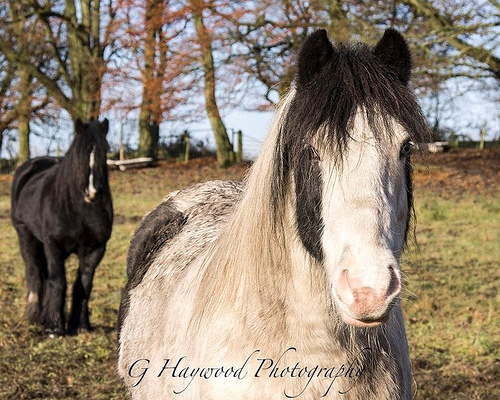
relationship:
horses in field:
[3, 66, 443, 317] [416, 180, 492, 331]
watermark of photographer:
[105, 353, 384, 387] [129, 357, 254, 391]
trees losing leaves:
[39, 17, 288, 108] [158, 10, 197, 20]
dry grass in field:
[437, 364, 493, 387] [416, 180, 492, 331]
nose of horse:
[341, 278, 392, 321] [272, 60, 424, 298]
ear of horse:
[297, 32, 339, 84] [272, 60, 424, 298]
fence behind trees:
[150, 130, 222, 150] [39, 17, 288, 108]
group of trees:
[16, 8, 219, 143] [39, 17, 288, 108]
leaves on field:
[158, 10, 197, 20] [416, 180, 492, 331]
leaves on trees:
[158, 10, 197, 20] [39, 17, 288, 108]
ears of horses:
[71, 99, 115, 134] [8, 116, 114, 336]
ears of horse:
[280, 22, 400, 65] [272, 60, 424, 298]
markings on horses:
[91, 141, 103, 198] [8, 116, 114, 336]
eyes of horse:
[270, 107, 445, 172] [272, 60, 424, 298]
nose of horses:
[84, 181, 125, 198] [8, 116, 114, 336]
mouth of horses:
[328, 310, 424, 325] [8, 116, 114, 336]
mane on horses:
[80, 124, 113, 143] [8, 116, 114, 336]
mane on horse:
[321, 62, 403, 88] [272, 60, 424, 298]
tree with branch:
[193, 10, 241, 155] [240, 13, 325, 32]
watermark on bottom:
[105, 353, 384, 387] [371, 390, 380, 393]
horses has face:
[8, 116, 114, 336] [73, 130, 111, 198]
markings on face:
[141, 202, 188, 245] [73, 130, 111, 198]